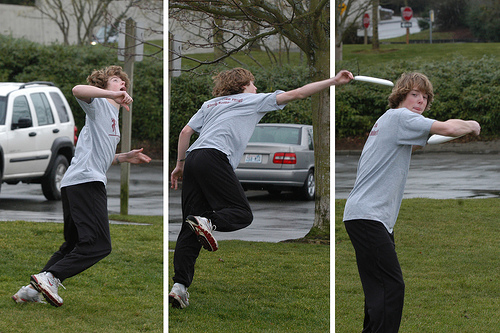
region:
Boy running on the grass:
[11, 66, 152, 303]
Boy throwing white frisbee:
[345, 69, 482, 331]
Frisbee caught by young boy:
[171, 66, 393, 328]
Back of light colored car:
[223, 117, 319, 201]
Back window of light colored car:
[239, 118, 305, 150]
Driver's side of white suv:
[0, 75, 81, 200]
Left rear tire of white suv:
[39, 149, 78, 200]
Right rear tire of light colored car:
[300, 162, 318, 199]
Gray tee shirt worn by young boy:
[340, 107, 435, 234]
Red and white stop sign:
[396, 0, 417, 27]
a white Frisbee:
[351, 69, 395, 91]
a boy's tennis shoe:
[28, 270, 70, 307]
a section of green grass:
[332, 200, 498, 330]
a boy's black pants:
[340, 215, 412, 331]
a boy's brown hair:
[384, 69, 435, 110]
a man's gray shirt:
[340, 106, 436, 241]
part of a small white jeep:
[0, 67, 80, 199]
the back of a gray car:
[237, 125, 322, 198]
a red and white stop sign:
[395, 5, 415, 23]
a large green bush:
[337, 40, 499, 138]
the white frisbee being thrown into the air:
[353, 75, 393, 86]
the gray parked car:
[235, 124, 314, 199]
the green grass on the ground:
[0, 198, 499, 332]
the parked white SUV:
[1, 80, 76, 200]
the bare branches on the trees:
[11, 0, 332, 74]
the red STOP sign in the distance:
[362, 12, 368, 45]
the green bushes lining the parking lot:
[1, 37, 498, 138]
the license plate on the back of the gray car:
[243, 152, 262, 162]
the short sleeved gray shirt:
[343, 107, 436, 234]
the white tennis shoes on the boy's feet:
[13, 270, 63, 309]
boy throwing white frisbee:
[357, 64, 449, 329]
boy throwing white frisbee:
[180, 56, 301, 307]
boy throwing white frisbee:
[54, 63, 154, 309]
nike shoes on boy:
[32, 271, 64, 303]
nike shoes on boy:
[1, 278, 55, 312]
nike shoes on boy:
[183, 211, 228, 263]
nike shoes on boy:
[172, 279, 196, 312]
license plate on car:
[238, 150, 274, 163]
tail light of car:
[275, 150, 308, 169]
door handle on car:
[21, 130, 40, 141]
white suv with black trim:
[1, 80, 67, 198]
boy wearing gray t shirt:
[56, 64, 136, 319]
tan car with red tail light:
[251, 121, 321, 210]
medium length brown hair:
[211, 63, 258, 99]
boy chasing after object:
[57, 61, 136, 261]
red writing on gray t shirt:
[197, 90, 252, 115]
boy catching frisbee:
[168, 63, 394, 310]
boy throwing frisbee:
[341, 75, 492, 330]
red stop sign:
[398, 5, 419, 21]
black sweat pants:
[339, 210, 414, 330]